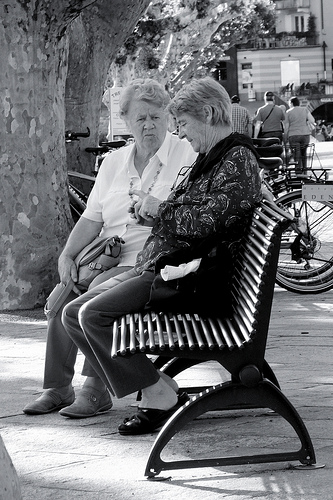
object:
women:
[60, 77, 262, 436]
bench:
[110, 199, 326, 482]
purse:
[74, 235, 126, 287]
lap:
[104, 235, 122, 259]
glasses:
[167, 160, 197, 202]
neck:
[205, 125, 231, 155]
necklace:
[128, 162, 160, 199]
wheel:
[262, 193, 333, 295]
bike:
[257, 156, 333, 295]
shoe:
[117, 392, 190, 436]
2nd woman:
[23, 75, 262, 435]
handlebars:
[65, 126, 91, 143]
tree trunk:
[0, 0, 75, 327]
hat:
[265, 91, 274, 99]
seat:
[99, 140, 127, 148]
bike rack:
[311, 257, 333, 265]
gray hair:
[119, 77, 168, 99]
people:
[231, 94, 253, 134]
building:
[273, 0, 332, 44]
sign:
[302, 185, 333, 201]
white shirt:
[81, 130, 199, 266]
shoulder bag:
[254, 104, 276, 138]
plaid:
[232, 104, 247, 134]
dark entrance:
[311, 101, 333, 126]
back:
[231, 200, 296, 359]